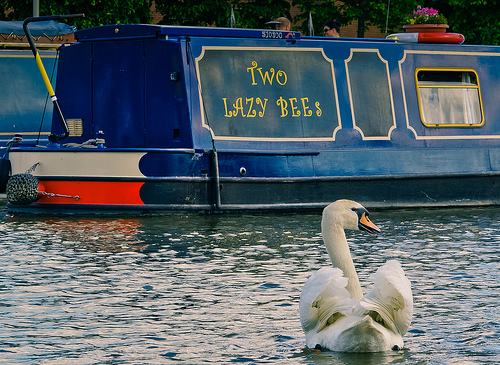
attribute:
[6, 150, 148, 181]
stripe — white, red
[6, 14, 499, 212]
boat — large, blue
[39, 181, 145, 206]
stripe — red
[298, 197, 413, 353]
swan — white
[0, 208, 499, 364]
water — rippled, rippling, ocean, sea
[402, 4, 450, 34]
plant — potted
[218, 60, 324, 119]
name — yellow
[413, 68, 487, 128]
window — opened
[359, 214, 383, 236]
beak — orange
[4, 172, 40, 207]
rope — bundled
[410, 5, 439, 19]
flowers — pink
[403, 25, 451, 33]
pot — brown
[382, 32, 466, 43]
life preserver — red, white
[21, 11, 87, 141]
pole — blue, yellow